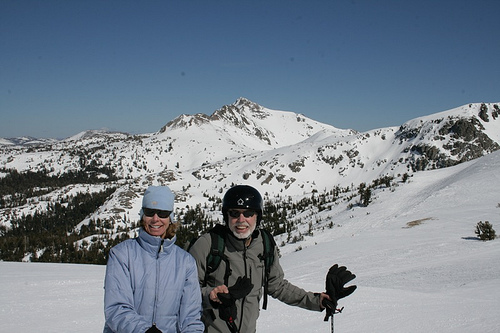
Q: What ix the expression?
A: Smiling.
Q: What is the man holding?
A: Gloves.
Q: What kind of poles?
A: Ski poles.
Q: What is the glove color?
A: Black.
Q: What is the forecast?
A: Clear blue skies.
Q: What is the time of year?
A: Winter.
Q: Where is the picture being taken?
A: On skii slopes.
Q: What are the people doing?
A: Skiing.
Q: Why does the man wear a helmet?
A: To protect the head.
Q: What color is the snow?
A: White.